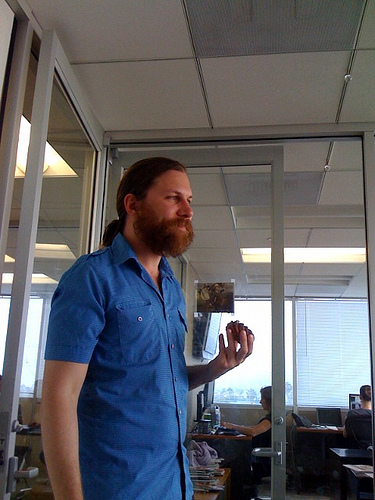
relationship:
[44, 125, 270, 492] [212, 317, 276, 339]
man eating doughnut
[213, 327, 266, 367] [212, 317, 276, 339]
hand holding doughnut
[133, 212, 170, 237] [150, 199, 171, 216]
bead covering cheeks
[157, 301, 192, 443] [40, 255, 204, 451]
buttons on shirt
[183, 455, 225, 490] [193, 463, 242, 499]
magazines on table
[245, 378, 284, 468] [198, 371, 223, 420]
woman at computer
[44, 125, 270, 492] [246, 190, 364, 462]
man at screen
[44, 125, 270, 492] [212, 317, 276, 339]
man holding object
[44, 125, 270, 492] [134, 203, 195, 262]
man with bead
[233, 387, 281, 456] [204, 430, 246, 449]
women sitting at desk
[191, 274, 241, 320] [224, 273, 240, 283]
image was taped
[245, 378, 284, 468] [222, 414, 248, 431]
woman was typing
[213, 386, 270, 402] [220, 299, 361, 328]
trees outside window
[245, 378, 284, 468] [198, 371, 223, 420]
woman working on computer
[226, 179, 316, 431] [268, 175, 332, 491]
newly opened door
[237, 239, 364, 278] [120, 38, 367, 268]
light of ceiling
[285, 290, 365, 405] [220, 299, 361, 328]
curtain in window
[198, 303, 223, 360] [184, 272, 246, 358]
tv on wall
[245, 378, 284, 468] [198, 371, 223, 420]
woman using computer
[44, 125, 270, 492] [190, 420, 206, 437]
man holding pinecone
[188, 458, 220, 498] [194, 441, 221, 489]
pile of papers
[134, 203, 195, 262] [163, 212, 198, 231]
bead with mustache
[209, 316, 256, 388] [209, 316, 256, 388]
hand hand hand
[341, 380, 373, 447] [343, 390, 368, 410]
office worker sits computer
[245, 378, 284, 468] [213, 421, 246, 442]
woman hands keyboard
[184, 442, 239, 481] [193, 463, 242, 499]
items on table